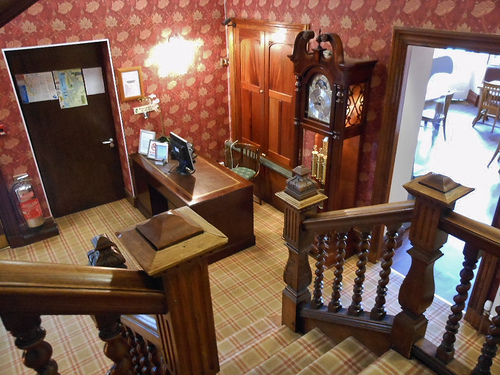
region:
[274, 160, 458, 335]
a wooden brown stair rail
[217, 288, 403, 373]
plaid carpet stairs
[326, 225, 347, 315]
a twisted wooden bannister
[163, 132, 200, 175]
a desktop computer moniter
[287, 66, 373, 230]
a big grandfather clock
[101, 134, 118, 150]
a chrome door knob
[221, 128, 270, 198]
a wooden chair with a green cusion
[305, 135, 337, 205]
clock gears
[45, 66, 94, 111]
a map on a door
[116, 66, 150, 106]
a picture frame on the wall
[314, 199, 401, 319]
a banister of a set of stairs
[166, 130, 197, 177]
a computer monitor on a desk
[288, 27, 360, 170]
a grandfather clock in a lobby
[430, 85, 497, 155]
table and chairs in dining room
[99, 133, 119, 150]
the handle of a door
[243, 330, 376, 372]
steps of a set of stairs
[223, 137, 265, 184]
a wooden chair with a seat cushion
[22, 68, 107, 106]
paper notices on a door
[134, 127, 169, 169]
notices in frames on a desk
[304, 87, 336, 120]
a face of a clock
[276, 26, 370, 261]
a brown old grandfather clock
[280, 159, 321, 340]
a wooden banister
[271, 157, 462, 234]
a brown wooden hand rail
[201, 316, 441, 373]
plaid covered carpet steps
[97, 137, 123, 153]
a silver door handle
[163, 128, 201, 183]
a desktop computer monitor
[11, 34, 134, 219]
a dark brown wooden door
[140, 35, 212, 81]
a bright light that is on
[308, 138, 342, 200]
gearing in a clock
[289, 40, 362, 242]
Grandfather clock near wall.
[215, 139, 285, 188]
Blue cushion on wood chair.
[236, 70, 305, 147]
Wooden cupboards behind chair.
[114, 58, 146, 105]
Wood frame hanging on wall.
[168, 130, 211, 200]
Desktop computer sitting on desk.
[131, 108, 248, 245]
Large wood desk in room.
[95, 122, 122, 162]
Silver handle on door.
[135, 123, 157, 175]
Papers framed on top of desk.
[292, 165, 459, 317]
Wood railing on stairs.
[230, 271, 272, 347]
Brown and red carpet in room.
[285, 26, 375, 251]
Decorative Antique grandfather clock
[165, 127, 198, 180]
an office workstation computer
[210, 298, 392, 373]
Carpeted stair case for customers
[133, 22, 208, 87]
Indoor lighting for receptionist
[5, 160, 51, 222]
Fire extinguisher for emergencies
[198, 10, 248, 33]
Hotel security camera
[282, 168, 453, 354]
Antique wooden stair rail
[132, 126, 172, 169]
Hotel brochures for guests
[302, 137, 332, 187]
Chimes for grandfather clock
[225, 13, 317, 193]
Wooden doorway to closet